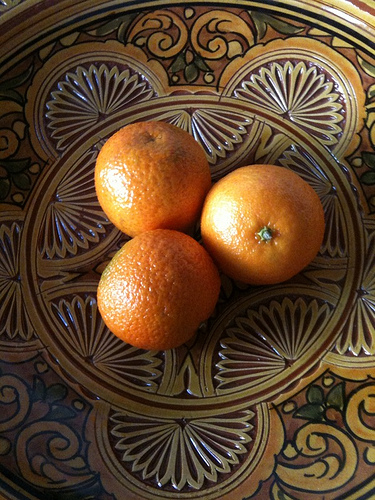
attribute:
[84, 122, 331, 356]
group — oranges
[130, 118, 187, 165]
spot — brown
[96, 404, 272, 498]
design — half moon shape, tile design, Shiny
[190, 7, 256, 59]
design — Curved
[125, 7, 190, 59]
design — Curved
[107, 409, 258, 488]
design — Peacock feather shaped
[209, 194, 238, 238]
reflection — Light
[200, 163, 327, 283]
skin — orange skin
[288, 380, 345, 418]
design — Painted, green leaf design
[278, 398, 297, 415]
design — Black outlined circle, circle design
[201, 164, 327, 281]
orange — fresh, small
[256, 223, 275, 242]
stem — green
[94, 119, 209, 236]
orange — light brown, fresh, small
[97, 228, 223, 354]
orange — fresh, bumpy, small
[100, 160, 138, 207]
reflection — light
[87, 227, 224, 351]
orange — small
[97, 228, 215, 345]
rind — speckled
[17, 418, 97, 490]
pattern — decorative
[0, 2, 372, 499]
plate — brown, decorative plate, shiny, ceramic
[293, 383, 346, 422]
pattern — leaf pattern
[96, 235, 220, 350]
orange — fresh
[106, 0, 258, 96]
paint — green, tan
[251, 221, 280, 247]
stem — green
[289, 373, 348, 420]
leaf — green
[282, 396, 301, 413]
design — small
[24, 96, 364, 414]
circle — decorative, big, large brown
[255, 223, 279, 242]
stem — green, hard